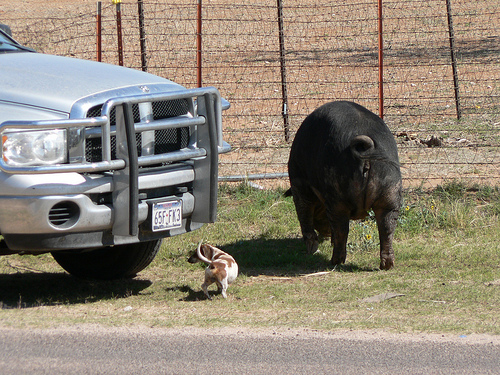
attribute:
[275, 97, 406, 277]
pig — big, black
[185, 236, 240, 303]
dog — small, brown, white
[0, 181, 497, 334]
grass — patchy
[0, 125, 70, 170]
headlight — clear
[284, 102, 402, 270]
pig — black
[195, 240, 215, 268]
tail — long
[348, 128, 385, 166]
tail — twisted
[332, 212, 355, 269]
legs — back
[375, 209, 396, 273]
legs — back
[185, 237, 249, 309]
dog — small, brown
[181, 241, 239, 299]
dog — small, white, brown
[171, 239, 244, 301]
dog — small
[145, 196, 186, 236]
plate — license